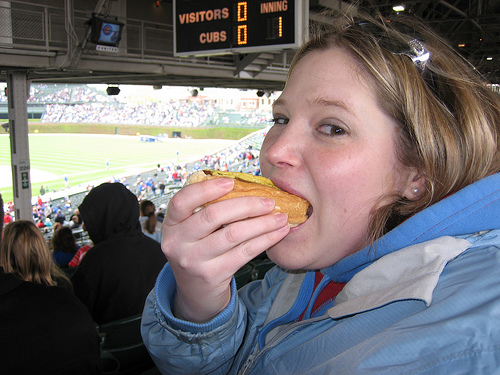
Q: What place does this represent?
A: It represents the stadium.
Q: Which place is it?
A: It is a stadium.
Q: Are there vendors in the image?
A: No, there are no vendors.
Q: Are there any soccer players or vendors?
A: No, there are no vendors or soccer players.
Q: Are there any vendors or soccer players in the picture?
A: No, there are no vendors or soccer players.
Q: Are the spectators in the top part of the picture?
A: Yes, the spectators are in the top of the image.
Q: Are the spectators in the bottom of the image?
A: No, the spectators are in the top of the image.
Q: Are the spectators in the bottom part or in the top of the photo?
A: The spectators are in the top of the image.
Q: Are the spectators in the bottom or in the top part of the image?
A: The spectators are in the top of the image.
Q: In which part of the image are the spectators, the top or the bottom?
A: The spectators are in the top of the image.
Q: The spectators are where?
A: The spectators are at the game.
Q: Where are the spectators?
A: The spectators are at the game.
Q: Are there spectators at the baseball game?
A: Yes, there are spectators at the game.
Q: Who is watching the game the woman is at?
A: The spectators are watching the game.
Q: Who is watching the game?
A: The spectators are watching the game.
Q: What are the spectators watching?
A: The spectators are watching the game.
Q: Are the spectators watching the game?
A: Yes, the spectators are watching the game.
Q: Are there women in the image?
A: Yes, there is a woman.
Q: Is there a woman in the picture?
A: Yes, there is a woman.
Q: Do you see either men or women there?
A: Yes, there is a woman.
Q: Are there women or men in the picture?
A: Yes, there is a woman.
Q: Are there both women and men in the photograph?
A: No, there is a woman but no men.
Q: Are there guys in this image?
A: No, there are no guys.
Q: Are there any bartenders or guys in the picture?
A: No, there are no guys or bartenders.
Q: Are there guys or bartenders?
A: No, there are no guys or bartenders.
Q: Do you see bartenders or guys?
A: No, there are no guys or bartenders.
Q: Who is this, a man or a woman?
A: This is a woman.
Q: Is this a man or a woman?
A: This is a woman.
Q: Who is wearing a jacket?
A: The woman is wearing a jacket.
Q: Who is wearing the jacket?
A: The woman is wearing a jacket.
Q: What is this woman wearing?
A: The woman is wearing a jacket.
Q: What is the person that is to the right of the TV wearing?
A: The woman is wearing a jacket.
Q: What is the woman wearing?
A: The woman is wearing a jacket.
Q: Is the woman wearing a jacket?
A: Yes, the woman is wearing a jacket.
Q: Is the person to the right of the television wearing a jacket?
A: Yes, the woman is wearing a jacket.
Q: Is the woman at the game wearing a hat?
A: No, the woman is wearing a jacket.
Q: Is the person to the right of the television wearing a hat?
A: No, the woman is wearing a jacket.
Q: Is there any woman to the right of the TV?
A: Yes, there is a woman to the right of the TV.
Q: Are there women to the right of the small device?
A: Yes, there is a woman to the right of the TV.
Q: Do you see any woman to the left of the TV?
A: No, the woman is to the right of the TV.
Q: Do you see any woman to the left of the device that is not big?
A: No, the woman is to the right of the TV.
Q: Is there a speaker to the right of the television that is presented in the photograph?
A: No, there is a woman to the right of the television.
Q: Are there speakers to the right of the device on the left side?
A: No, there is a woman to the right of the television.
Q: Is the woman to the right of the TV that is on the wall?
A: Yes, the woman is to the right of the television.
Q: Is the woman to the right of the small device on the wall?
A: Yes, the woman is to the right of the television.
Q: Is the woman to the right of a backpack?
A: No, the woman is to the right of the television.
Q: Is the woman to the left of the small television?
A: No, the woman is to the right of the TV.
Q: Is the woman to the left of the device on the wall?
A: No, the woman is to the right of the TV.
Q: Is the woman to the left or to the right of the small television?
A: The woman is to the right of the television.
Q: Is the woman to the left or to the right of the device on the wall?
A: The woman is to the right of the television.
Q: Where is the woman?
A: The woman is at the game.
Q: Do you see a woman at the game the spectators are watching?
A: Yes, there is a woman at the game.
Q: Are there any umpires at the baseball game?
A: No, there is a woman at the game.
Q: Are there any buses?
A: No, there are no buses.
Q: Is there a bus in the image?
A: No, there are no buses.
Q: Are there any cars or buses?
A: No, there are no buses or cars.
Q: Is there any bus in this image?
A: No, there are no buses.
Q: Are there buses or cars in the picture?
A: No, there are no buses or cars.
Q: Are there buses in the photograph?
A: No, there are no buses.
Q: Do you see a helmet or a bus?
A: No, there are no buses or helmets.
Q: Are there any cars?
A: No, there are no cars.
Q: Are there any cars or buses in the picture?
A: No, there are no cars or buses.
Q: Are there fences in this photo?
A: No, there are no fences.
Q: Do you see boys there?
A: No, there are no boys.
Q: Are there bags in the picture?
A: No, there are no bags.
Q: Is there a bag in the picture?
A: No, there are no bags.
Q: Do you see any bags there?
A: No, there are no bags.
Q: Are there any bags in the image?
A: No, there are no bags.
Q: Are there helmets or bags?
A: No, there are no bags or helmets.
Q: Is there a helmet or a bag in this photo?
A: No, there are no bags or helmets.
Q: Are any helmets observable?
A: No, there are no helmets.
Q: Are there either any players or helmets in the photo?
A: No, there are no helmets or players.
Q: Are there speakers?
A: No, there are no speakers.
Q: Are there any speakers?
A: No, there are no speakers.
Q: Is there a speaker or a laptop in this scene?
A: No, there are no speakers or laptops.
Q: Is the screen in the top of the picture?
A: Yes, the screen is in the top of the image.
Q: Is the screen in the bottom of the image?
A: No, the screen is in the top of the image.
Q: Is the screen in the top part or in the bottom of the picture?
A: The screen is in the top of the image.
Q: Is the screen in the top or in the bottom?
A: The screen is in the top of the image.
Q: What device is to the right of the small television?
A: The device is a screen.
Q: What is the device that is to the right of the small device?
A: The device is a screen.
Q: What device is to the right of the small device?
A: The device is a screen.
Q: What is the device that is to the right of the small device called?
A: The device is a screen.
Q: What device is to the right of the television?
A: The device is a screen.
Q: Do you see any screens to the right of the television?
A: Yes, there is a screen to the right of the television.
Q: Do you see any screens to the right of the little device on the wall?
A: Yes, there is a screen to the right of the television.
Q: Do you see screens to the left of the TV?
A: No, the screen is to the right of the TV.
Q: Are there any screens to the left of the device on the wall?
A: No, the screen is to the right of the TV.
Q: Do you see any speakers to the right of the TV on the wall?
A: No, there is a screen to the right of the television.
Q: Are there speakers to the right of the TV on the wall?
A: No, there is a screen to the right of the television.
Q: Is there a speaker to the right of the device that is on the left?
A: No, there is a screen to the right of the television.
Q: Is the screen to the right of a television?
A: Yes, the screen is to the right of a television.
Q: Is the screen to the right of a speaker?
A: No, the screen is to the right of a television.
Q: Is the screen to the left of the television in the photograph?
A: No, the screen is to the right of the television.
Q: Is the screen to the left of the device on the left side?
A: No, the screen is to the right of the television.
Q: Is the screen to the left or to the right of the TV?
A: The screen is to the right of the TV.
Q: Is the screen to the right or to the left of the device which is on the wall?
A: The screen is to the right of the TV.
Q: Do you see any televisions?
A: Yes, there is a television.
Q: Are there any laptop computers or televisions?
A: Yes, there is a television.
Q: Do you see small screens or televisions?
A: Yes, there is a small television.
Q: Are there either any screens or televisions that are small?
A: Yes, the television is small.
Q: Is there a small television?
A: Yes, there is a small television.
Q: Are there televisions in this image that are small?
A: Yes, there is a television that is small.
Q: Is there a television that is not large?
A: Yes, there is a small television.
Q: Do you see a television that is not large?
A: Yes, there is a small television.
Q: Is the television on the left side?
A: Yes, the television is on the left of the image.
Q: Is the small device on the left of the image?
A: Yes, the television is on the left of the image.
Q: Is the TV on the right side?
A: No, the TV is on the left of the image.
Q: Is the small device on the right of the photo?
A: No, the TV is on the left of the image.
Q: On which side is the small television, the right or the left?
A: The television is on the left of the image.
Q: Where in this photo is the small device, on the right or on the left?
A: The television is on the left of the image.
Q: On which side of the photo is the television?
A: The television is on the left of the image.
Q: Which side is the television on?
A: The television is on the left of the image.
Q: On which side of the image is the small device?
A: The television is on the left of the image.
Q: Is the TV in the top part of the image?
A: Yes, the TV is in the top of the image.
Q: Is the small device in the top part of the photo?
A: Yes, the TV is in the top of the image.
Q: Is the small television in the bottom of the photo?
A: No, the TV is in the top of the image.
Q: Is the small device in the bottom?
A: No, the TV is in the top of the image.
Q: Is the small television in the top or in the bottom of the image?
A: The TV is in the top of the image.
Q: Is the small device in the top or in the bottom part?
A: The TV is in the top of the image.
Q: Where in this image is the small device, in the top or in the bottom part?
A: The TV is in the top of the image.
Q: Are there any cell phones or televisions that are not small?
A: No, there is a television but it is small.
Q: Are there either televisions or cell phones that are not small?
A: No, there is a television but it is small.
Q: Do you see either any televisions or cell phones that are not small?
A: No, there is a television but it is small.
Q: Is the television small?
A: Yes, the television is small.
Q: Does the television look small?
A: Yes, the television is small.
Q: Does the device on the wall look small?
A: Yes, the television is small.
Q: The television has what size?
A: The television is small.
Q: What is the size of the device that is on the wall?
A: The television is small.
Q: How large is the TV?
A: The TV is small.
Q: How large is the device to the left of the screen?
A: The TV is small.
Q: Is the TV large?
A: No, the TV is small.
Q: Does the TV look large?
A: No, the TV is small.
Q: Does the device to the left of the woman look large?
A: No, the TV is small.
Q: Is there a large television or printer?
A: No, there is a television but it is small.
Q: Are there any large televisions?
A: No, there is a television but it is small.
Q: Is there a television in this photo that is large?
A: No, there is a television but it is small.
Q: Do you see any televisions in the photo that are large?
A: No, there is a television but it is small.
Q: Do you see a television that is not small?
A: No, there is a television but it is small.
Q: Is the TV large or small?
A: The TV is small.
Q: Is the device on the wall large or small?
A: The TV is small.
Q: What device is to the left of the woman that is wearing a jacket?
A: The device is a television.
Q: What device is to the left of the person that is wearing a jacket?
A: The device is a television.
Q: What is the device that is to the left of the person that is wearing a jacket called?
A: The device is a television.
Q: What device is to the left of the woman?
A: The device is a television.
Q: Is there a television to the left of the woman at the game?
A: Yes, there is a television to the left of the woman.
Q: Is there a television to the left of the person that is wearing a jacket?
A: Yes, there is a television to the left of the woman.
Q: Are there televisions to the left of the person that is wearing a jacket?
A: Yes, there is a television to the left of the woman.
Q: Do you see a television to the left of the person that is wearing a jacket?
A: Yes, there is a television to the left of the woman.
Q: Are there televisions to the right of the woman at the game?
A: No, the television is to the left of the woman.